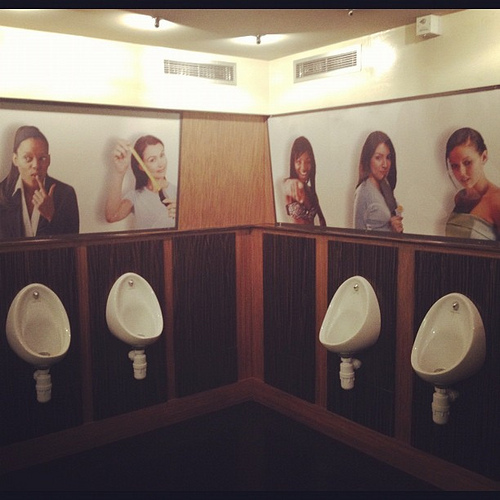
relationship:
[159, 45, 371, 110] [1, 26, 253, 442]
plates on wall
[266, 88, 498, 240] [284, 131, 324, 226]
picture of woman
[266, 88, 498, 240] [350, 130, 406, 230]
picture of woman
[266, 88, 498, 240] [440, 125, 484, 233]
picture of woman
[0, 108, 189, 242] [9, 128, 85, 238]
picture of woman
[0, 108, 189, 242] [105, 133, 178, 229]
picture of woman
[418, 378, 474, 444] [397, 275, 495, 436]
pipe under urinal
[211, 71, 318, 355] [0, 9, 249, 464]
corner of wall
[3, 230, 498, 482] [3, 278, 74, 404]
panels behind urinal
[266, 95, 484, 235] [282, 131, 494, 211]
picture of woman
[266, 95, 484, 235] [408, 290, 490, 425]
picture in front of urinal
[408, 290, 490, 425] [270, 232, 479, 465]
urinal on wall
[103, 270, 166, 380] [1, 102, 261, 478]
urinal on wall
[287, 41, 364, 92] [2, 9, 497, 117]
vent on wall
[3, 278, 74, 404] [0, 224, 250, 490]
urinal on wall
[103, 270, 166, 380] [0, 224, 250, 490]
urinal on wall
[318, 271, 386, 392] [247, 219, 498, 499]
urinal on wall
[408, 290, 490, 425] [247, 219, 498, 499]
urinal on wall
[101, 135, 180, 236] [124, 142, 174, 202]
woman has tape measure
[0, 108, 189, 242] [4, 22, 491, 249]
picture are on walls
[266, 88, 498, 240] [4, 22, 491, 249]
picture are on walls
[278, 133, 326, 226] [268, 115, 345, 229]
woman pointing in picture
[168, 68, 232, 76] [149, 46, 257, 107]
vent on wall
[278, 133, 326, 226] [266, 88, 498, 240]
woman in picture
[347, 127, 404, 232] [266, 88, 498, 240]
woman in picture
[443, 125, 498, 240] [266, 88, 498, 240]
woman in picture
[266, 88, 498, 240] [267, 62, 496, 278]
picture on wall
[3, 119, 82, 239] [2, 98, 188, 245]
women in picture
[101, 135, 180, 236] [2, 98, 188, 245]
woman in picture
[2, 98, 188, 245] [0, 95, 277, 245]
picture on wall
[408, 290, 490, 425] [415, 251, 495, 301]
urinal on wall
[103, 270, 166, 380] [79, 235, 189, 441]
urinal on wall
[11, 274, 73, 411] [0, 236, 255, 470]
urinal on wall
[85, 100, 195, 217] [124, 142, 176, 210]
woman holding tape measure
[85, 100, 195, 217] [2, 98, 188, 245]
woman in picture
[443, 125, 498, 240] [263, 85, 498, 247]
woman in picture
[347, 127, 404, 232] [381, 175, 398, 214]
woman holding knife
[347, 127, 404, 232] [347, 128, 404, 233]
woman in picture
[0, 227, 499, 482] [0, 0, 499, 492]
wood panels on wall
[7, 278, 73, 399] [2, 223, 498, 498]
urinal on wall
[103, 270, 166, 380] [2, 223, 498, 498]
urinal on wall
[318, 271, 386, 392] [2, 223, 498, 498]
urinal on wall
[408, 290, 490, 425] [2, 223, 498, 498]
urinal on wall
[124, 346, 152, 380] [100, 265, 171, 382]
pipe under urinal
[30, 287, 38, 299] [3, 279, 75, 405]
button on urinal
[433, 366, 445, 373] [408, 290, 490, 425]
drain in urinal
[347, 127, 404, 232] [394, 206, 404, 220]
woman holding object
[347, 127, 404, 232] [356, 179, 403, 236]
woman wearing blue shirt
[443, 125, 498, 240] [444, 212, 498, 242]
woman wearing gown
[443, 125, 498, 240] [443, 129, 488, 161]
woman wearing hair bun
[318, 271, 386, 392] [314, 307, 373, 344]
urinal has bowl